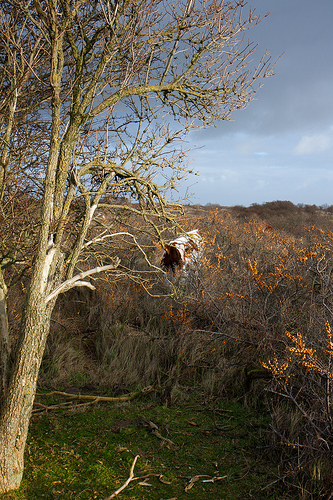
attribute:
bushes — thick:
[4, 183, 321, 491]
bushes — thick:
[9, 175, 306, 497]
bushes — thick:
[140, 259, 239, 320]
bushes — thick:
[137, 251, 232, 317]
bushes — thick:
[141, 234, 234, 308]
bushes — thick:
[175, 241, 234, 308]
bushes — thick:
[156, 237, 237, 320]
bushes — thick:
[169, 238, 226, 304]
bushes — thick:
[177, 244, 226, 300]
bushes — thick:
[174, 236, 226, 295]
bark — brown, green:
[3, 305, 45, 492]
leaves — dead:
[262, 354, 296, 381]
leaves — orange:
[286, 330, 312, 362]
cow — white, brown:
[160, 221, 207, 287]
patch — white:
[167, 236, 186, 258]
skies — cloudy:
[189, 12, 331, 177]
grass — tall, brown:
[71, 305, 161, 382]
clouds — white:
[180, 151, 219, 185]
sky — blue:
[190, 119, 317, 200]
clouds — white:
[281, 141, 324, 176]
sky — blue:
[223, 130, 331, 201]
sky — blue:
[187, 138, 279, 178]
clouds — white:
[181, 116, 319, 199]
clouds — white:
[243, 174, 270, 193]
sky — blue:
[220, 142, 290, 185]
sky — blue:
[281, 134, 310, 172]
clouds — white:
[249, 124, 314, 173]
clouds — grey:
[282, 36, 321, 92]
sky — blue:
[247, 76, 332, 187]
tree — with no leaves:
[2, 3, 277, 494]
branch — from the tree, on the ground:
[99, 454, 144, 497]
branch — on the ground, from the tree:
[40, 382, 156, 411]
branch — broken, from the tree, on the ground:
[36, 385, 154, 409]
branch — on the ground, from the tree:
[141, 414, 174, 454]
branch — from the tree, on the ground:
[30, 386, 137, 412]